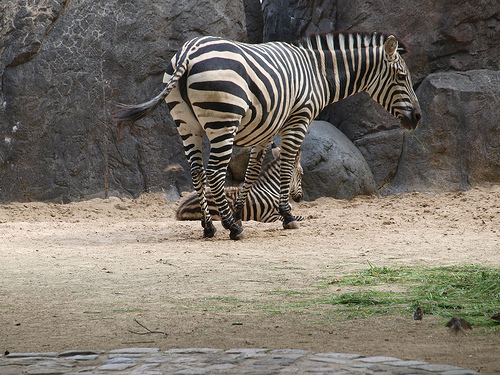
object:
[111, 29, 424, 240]
zebra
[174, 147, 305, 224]
zebra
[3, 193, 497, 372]
ground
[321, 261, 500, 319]
grass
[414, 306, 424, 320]
bird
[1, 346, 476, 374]
stones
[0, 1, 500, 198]
wall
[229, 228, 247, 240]
hoof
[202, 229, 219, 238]
hoof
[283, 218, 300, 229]
hoof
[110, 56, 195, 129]
tail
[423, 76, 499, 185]
boulder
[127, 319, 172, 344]
stick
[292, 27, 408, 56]
mane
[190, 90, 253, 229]
leg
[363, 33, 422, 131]
head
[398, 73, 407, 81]
eye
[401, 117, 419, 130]
mouth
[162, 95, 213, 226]
leg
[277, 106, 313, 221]
leg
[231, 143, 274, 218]
leg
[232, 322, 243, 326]
leaves